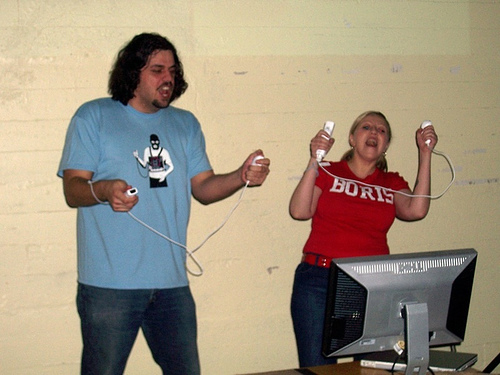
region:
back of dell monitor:
[321, 245, 477, 373]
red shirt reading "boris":
[300, 154, 417, 264]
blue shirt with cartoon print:
[55, 92, 217, 294]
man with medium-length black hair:
[46, 25, 272, 372]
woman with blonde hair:
[283, 106, 439, 372]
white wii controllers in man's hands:
[82, 144, 272, 287]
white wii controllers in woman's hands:
[311, 116, 458, 203]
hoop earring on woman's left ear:
[381, 149, 391, 156]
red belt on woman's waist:
[298, 248, 344, 270]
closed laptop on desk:
[356, 347, 483, 374]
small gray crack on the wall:
[243, 262, 297, 280]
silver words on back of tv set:
[384, 255, 444, 285]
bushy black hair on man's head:
[93, 16, 203, 102]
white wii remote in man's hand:
[105, 176, 213, 198]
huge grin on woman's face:
[343, 131, 402, 159]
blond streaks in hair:
[348, 95, 373, 127]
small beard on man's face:
[137, 95, 189, 117]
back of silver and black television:
[315, 238, 496, 353]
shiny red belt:
[281, 245, 363, 266]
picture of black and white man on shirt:
[120, 131, 202, 220]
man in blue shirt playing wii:
[58, 33, 271, 365]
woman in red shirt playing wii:
[291, 108, 456, 256]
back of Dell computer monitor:
[324, 248, 479, 370]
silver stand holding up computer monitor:
[402, 299, 432, 373]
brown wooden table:
[285, 360, 371, 373]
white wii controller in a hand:
[313, 120, 336, 165]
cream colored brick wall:
[219, 56, 306, 128]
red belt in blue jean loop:
[298, 248, 334, 267]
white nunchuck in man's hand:
[238, 148, 273, 192]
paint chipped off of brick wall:
[385, 58, 407, 78]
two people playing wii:
[64, 23, 475, 343]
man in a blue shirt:
[49, 25, 271, 306]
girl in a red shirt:
[294, 100, 464, 287]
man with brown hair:
[67, 9, 240, 134]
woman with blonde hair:
[332, 82, 419, 182]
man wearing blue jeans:
[59, 18, 260, 358]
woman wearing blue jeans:
[292, 87, 452, 356]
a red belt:
[279, 240, 393, 279]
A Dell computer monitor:
[319, 223, 490, 363]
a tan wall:
[217, 41, 469, 138]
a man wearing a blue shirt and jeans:
[52, 23, 271, 373]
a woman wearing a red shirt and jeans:
[284, 99, 456, 369]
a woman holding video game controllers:
[285, 101, 460, 373]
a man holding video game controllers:
[51, 28, 273, 369]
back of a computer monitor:
[318, 246, 479, 369]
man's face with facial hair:
[103, 27, 194, 114]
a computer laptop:
[352, 346, 482, 371]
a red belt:
[295, 247, 332, 270]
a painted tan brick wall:
[0, 2, 499, 365]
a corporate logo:
[395, 259, 427, 276]